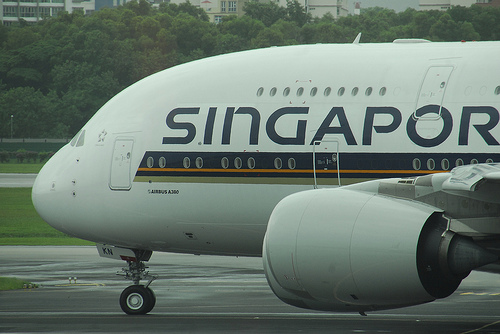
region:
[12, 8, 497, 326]
An airplane on the runway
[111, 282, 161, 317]
Round wheels under the airplane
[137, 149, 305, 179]
Many windows on side of the plane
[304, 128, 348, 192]
A door on the side of the plane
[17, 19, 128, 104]
Green leaves on many trees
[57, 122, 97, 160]
Front windows of the plane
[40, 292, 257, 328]
White line on the ground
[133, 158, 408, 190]
Yellow line on side of the plane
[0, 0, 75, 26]
Windows on a building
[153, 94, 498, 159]
Letters on side of the plane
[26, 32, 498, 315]
A large airplane on the ground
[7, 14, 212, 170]
Trees in the distance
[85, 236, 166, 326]
The wheels in the front of an airplane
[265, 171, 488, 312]
An engine on an airplane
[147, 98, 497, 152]
The word Singapor on the side of a plane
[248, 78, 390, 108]
Windows on an airplane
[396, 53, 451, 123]
A door on an airplane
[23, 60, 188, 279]
The nose of an airplane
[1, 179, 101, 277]
Grass near the pavement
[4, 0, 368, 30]
Buildings beyond the trees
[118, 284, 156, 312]
wheel of airplane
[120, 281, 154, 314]
black wheel with white center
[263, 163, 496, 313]
wing of airplane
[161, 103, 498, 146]
the words SINGAPOR on the airplane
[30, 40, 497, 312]
big, white airplane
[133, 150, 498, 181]
blue, orange and gold stripe on the side of plane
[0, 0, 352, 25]
buildings behind the trees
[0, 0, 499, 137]
trees in the distances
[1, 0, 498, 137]
the green trees in the distance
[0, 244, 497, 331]
runway for airplane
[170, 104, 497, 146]
Black writting of plane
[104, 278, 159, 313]
Wheel of the plane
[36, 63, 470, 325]
A white Aeroplane landing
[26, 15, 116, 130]
A Green thick forest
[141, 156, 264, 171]
Window of an Aeroplane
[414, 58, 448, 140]
A door of an Aeroplane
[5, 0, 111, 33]
Buildings apprearing above the forest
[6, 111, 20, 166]
Pole on the fance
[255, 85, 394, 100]
Ventilations on the plane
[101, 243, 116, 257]
Model of the plane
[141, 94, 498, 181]
word on the plane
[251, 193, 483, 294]
engine of the plane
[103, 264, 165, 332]
wheel on front of plane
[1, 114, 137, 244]
nose of the plane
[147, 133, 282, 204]
windows on the plane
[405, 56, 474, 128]
door on side of plane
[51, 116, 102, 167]
front window of plane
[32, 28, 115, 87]
trees in the distance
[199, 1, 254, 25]
windows on the building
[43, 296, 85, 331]
runway under the plane